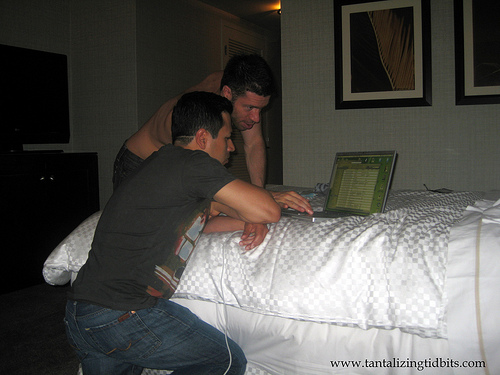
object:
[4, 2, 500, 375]
photo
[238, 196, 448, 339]
bed spread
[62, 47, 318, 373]
two males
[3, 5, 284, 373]
background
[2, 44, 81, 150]
television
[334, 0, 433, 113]
art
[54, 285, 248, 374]
jeans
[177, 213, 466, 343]
cover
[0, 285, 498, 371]
floor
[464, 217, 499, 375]
trim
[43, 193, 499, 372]
sheets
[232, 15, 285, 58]
top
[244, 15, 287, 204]
door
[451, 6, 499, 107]
picture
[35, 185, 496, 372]
spread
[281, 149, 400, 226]
computer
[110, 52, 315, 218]
man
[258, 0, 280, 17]
light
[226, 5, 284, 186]
hall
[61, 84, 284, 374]
man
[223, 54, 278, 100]
hair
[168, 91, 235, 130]
hair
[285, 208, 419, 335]
comforter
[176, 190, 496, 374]
bed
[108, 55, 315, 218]
guy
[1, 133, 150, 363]
dresser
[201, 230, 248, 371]
power cord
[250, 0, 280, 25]
ceiling light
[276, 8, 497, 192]
wall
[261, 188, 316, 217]
hand